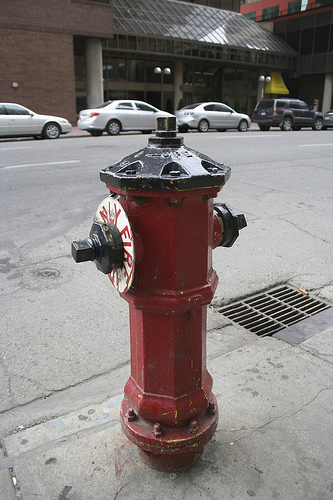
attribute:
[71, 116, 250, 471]
hydrant — red, black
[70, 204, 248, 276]
bolts — black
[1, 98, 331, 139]
cars — parked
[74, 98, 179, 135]
car — white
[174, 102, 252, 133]
car — silver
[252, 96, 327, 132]
vehicle — black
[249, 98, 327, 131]
suv — black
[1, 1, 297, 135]
building — glass, commercial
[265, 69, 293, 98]
canopy — yellow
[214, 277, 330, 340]
cover — storm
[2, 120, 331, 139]
sidewalk — concrete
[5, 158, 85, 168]
markings — white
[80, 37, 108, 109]
pillar — concrete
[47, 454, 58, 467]
mark — black